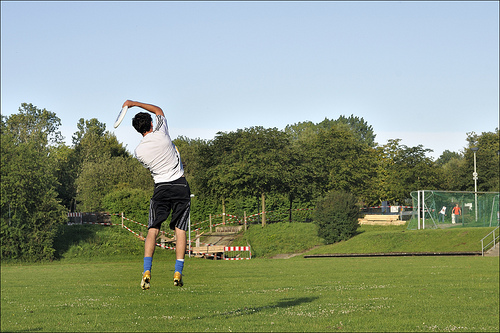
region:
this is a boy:
[123, 90, 209, 282]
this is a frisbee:
[109, 104, 129, 131]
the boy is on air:
[123, 98, 192, 288]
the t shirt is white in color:
[146, 140, 173, 175]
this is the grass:
[339, 260, 406, 330]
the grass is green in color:
[374, 263, 435, 330]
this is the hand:
[140, 93, 165, 111]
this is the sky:
[240, 3, 350, 80]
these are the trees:
[245, 129, 328, 176]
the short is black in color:
[153, 180, 192, 222]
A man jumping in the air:
[110, 98, 196, 285]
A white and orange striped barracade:
[223, 244, 251, 260]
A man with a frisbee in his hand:
[112, 101, 189, 286]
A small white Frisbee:
[112, 105, 127, 128]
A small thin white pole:
[472, 155, 477, 224]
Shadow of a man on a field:
[192, 295, 319, 320]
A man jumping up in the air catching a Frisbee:
[115, 100, 190, 288]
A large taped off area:
[122, 205, 257, 257]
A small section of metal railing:
[477, 225, 498, 253]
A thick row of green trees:
[0, 108, 499, 255]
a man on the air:
[94, 65, 207, 282]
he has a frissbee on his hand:
[73, 73, 210, 327]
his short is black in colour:
[148, 171, 205, 229]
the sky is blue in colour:
[176, 34, 306, 100]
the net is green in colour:
[406, 175, 498, 240]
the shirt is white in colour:
[126, 130, 196, 180]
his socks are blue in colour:
[135, 246, 192, 271]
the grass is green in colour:
[253, 278, 498, 332]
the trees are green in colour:
[223, 112, 360, 238]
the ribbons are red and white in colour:
[210, 205, 257, 277]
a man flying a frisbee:
[21, 48, 499, 293]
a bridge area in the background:
[186, 206, 266, 287]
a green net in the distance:
[404, 177, 499, 246]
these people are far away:
[437, 197, 464, 222]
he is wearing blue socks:
[117, 244, 202, 274]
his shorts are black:
[144, 174, 196, 239]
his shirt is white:
[118, 112, 191, 179]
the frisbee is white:
[103, 88, 133, 133]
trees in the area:
[201, 114, 375, 213]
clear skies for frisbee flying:
[72, 35, 442, 90]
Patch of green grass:
[22, 290, 62, 330]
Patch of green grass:
[90, 295, 134, 330]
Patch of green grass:
[140, 288, 165, 309]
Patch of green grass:
[211, 290, 251, 330]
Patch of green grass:
[277, 282, 307, 325]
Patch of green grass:
[319, 267, 374, 324]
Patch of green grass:
[410, 282, 442, 317]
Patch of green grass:
[457, 276, 496, 331]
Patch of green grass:
[397, 254, 417, 299]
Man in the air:
[92, 75, 205, 332]